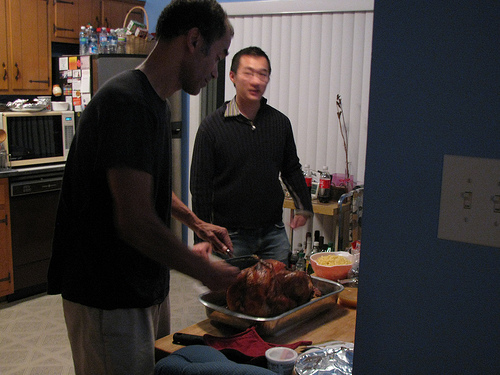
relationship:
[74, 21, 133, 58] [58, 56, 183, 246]
bottles on refrigerator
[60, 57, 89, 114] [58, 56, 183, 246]
notes on refrigerator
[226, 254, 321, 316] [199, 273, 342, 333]
turkey in pan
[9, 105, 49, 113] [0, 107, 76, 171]
dish on microwave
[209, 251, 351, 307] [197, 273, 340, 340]
turkey in pan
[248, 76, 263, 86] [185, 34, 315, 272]
nose on man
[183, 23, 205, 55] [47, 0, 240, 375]
ear on man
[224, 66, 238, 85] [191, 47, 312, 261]
ear on man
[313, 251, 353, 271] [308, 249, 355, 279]
food in bowl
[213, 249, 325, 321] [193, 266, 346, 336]
chicken in tray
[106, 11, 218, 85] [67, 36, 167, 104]
basket on top of fridge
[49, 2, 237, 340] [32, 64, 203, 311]
man wearing shirt